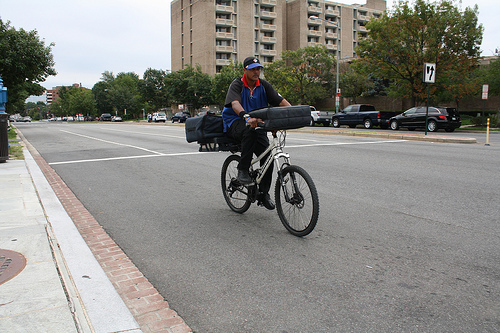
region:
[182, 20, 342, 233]
a pizza delivery man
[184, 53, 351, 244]
a man on a bicycle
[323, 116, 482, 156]
a raised median in street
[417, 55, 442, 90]
a white and black sign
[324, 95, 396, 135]
a dark colored truck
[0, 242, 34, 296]
a man hole cover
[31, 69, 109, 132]
a red brick building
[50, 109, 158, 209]
white lines on the pavement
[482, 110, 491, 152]
a bright yellow pole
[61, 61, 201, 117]
a variety of trees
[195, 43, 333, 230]
person riding a bike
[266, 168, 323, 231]
wheels on the bike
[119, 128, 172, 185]
lines on the street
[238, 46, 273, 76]
hat on man's head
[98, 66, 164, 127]
trees next to the street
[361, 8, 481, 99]
green tree next to street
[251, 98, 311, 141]
black delivery case on bike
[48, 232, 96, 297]
gray sidewalk next to street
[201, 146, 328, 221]
white bike with black wheels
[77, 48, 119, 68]
white sky above street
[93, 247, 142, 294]
edge of a road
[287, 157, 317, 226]
part of a wheel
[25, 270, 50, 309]
part of a floor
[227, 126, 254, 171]
part of a trouser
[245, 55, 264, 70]
a black red white and yellow baseball cap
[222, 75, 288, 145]
a black red white and yellow work shirt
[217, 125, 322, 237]
a black and white bike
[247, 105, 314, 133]
a black soft sided pizza carrier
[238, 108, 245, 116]
a black wristband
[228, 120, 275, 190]
a pair of black pants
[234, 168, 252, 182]
a black shoe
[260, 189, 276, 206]
a black shoe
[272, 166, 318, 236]
a black wheel of a bike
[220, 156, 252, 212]
a black wheel of a bike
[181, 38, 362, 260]
Man is riding a bike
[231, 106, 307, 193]
The bike's color is silver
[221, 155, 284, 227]
Man's shoes are black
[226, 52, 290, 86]
Man is wearing a cap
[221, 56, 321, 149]
Man is carrying a pizza on a bike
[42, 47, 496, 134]
Trees are in the background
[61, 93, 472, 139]
Cars are in the background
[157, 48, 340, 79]
Building is in the background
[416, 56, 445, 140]
A white traffic sign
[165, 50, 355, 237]
Young Man is riding a bike in the street